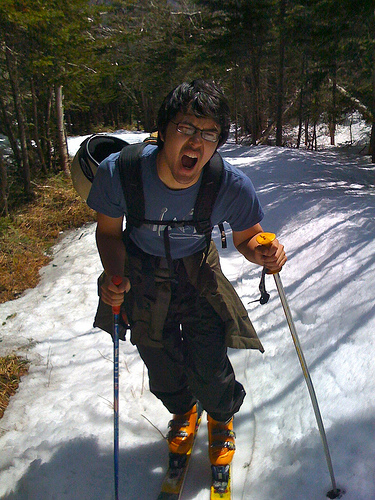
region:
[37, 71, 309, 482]
THIS IS A PERSON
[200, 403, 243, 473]
This is a shoe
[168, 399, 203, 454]
This is a shoe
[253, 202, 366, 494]
this is a ski rod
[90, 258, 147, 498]
this is a ski rod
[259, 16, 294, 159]
this is a tree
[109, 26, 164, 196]
this is a tree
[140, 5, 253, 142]
this is a tree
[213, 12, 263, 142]
this is a tree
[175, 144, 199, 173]
person's mouth is open.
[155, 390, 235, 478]
the boots are orange.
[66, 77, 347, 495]
the man is skiing.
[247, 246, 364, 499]
person holding a ski pole.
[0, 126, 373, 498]
snow covering the ground.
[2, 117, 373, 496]
the snow is white.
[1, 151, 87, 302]
the grass is brown.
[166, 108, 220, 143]
man is wearing glasses.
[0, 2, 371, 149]
trees behind the man.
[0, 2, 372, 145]
the trees are green.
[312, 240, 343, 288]
Part of the snow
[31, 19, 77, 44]
Part of the green tree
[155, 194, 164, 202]
Part of the blue shirt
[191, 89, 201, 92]
Part of the hair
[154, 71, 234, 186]
The head of the person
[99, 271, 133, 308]
The right hand of the person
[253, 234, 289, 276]
The left hand of the person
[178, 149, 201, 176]
The mouth of the person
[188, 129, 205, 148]
The nose of the person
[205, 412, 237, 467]
The left foot of the person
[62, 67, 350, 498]
A man in the foreground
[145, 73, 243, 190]
Man is wearing eyeglasses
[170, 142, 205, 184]
Man has his mouth open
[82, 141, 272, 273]
Man is wearing a blue shirt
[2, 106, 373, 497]
Snow is on the ground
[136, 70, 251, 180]
Man has dark colored hair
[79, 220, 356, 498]
Man is holding ski poles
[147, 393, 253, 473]
Man has orange colored shoes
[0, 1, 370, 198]
Tall trees in the background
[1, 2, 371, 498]
Photo was taken in the daytime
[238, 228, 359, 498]
ski pole with yellow top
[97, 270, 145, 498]
ski pole with red top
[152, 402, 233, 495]
pair of orange and yellow skis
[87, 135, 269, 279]
blue short sleeve shirt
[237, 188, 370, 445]
black shadow of trees in white snow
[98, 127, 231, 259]
black straps of black back pack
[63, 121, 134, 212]
helmet attached to person's back pack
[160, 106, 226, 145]
pair of black framed glasses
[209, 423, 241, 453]
two black straps across orange snow shoe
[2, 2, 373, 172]
tall green trees lining snow covered path